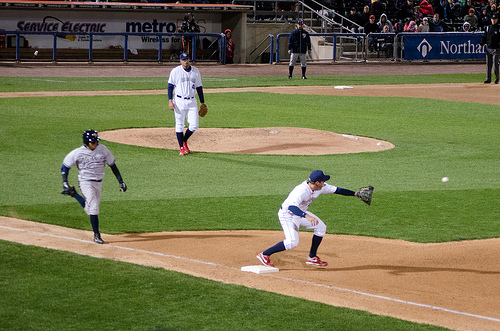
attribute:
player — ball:
[49, 125, 130, 251]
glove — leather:
[350, 169, 410, 224]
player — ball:
[256, 169, 373, 273]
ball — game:
[439, 176, 449, 185]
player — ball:
[164, 48, 214, 157]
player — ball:
[263, 160, 356, 263]